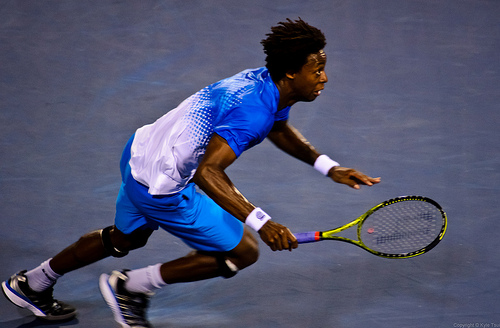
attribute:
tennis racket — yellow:
[283, 195, 463, 273]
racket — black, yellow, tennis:
[281, 196, 448, 259]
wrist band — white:
[240, 203, 273, 232]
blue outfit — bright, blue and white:
[113, 64, 278, 260]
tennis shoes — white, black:
[6, 278, 75, 322]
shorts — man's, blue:
[102, 134, 244, 261]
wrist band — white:
[311, 153, 338, 177]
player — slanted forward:
[8, 18, 487, 317]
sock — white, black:
[23, 255, 64, 292]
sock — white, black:
[120, 260, 167, 297]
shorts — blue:
[112, 134, 241, 253]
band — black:
[198, 254, 242, 286]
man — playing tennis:
[8, 15, 382, 326]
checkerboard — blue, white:
[148, 72, 284, 164]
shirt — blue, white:
[121, 76, 298, 196]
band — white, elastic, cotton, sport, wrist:
[245, 207, 270, 230]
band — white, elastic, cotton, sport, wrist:
[313, 154, 339, 176]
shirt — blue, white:
[117, 62, 292, 207]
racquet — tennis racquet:
[296, 195, 451, 257]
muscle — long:
[196, 176, 249, 222]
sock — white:
[25, 260, 58, 292]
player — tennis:
[3, 19, 383, 325]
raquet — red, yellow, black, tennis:
[292, 194, 444, 274]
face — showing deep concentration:
[253, 28, 374, 125]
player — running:
[95, 53, 297, 258]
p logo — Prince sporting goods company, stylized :
[369, 165, 472, 282]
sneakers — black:
[2, 265, 81, 321]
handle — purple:
[290, 230, 316, 244]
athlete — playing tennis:
[19, 19, 391, 326]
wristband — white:
[239, 203, 269, 231]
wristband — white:
[315, 146, 335, 176]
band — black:
[87, 211, 138, 268]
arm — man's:
[193, 125, 302, 251]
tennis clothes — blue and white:
[111, 64, 291, 252]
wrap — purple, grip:
[280, 225, 327, 248]